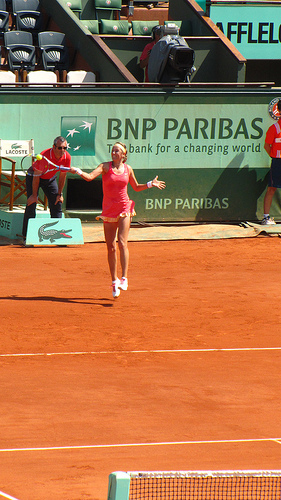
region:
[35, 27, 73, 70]
a chair in the stands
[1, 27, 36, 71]
a chair in the stands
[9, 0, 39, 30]
a chair in the stands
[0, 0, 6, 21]
a chair in the stands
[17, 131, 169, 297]
a tennis player hitting the ball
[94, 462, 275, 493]
a tennis net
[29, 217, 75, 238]
a logo advertisement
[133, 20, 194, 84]
a cameraman filming the match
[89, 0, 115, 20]
a chair in the stands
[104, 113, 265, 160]
a promotional advertisement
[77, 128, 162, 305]
blond woman playing tennis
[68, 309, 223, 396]
tennis court surface is orange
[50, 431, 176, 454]
white lines are on the tennis court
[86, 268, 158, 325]
woman is in mid air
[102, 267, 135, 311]
woman wearing white tennis shoes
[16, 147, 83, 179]
woman holding tennis racket in right hand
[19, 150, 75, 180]
racket will hit the ball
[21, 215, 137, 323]
woman's shadow is to her right on the ground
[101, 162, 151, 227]
woman is wearing a pink tank top style dress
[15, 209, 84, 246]
alligator graphic symbol of lacoste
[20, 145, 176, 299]
a tennis player hitting a ball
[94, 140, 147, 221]
a woman wearing red short dress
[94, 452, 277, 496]
a tennis court net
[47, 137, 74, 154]
man wearing dark sunglasses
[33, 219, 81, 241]
a painted crocodile with a red mouth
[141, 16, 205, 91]
a cameraman filming a tennis match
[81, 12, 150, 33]
a row of empty green seats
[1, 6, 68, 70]
four empty black seats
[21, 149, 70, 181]
a white and blue tennis racket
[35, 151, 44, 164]
a yellow tennis ball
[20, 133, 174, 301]
A PICTURE OF A WOMAN PLAYING TENNIS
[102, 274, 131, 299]
A PAIR OF WHITE SNEAKERS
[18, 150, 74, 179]
A TENNIS RACKET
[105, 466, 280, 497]
A TENNIS NET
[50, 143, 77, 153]
A PAIR OF SUNGLASSES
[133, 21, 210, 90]
A MAN RECORDING THE TENNIS MATCH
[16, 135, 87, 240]
A MAN WATCHING THE GAME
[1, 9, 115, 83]
SEATS IN THE STANDS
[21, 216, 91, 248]
A PICTURE OF AN ALLIGATOR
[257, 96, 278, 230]
A PERSON STANDING ON THE RIGHT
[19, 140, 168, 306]
woman playing tennis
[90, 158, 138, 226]
woman wearing a pink tennis dress with orange detail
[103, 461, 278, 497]
tennis net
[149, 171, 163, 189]
fingers of woman's left hand are spread out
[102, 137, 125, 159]
woman is wearing a headband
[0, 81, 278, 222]
wall behind woman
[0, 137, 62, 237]
chair on raised platform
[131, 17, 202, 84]
person operating large recording camera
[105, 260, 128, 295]
woman wearing white shoes with pink laces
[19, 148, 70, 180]
tennis racket in close proximity to tennis ball